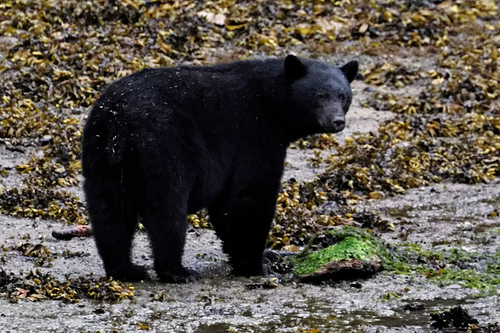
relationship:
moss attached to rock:
[305, 237, 368, 276] [289, 231, 385, 283]